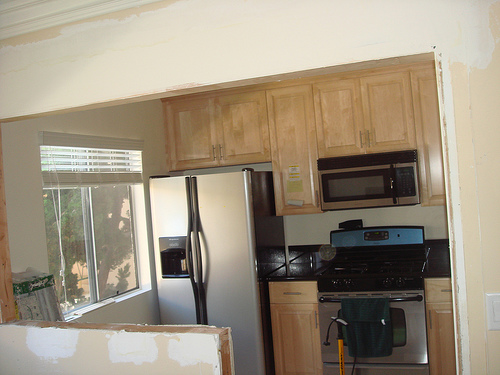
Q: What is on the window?
A: Shades.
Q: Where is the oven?
A: In a room.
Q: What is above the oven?
A: Microwave.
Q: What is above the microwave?
A: Cabinets.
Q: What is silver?
A: The fridge.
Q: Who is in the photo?
A: No people.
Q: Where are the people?
A: None in photo.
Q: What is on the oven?
A: Towel.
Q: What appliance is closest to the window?
A: Refrigerator.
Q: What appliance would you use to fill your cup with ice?
A: The freezer door by the window.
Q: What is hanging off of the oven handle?
A: Green towel.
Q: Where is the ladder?
A: Against the wall by the window.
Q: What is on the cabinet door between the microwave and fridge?
A: Stickers.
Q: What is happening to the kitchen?
A: Remodel.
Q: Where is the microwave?
A: Above the stove.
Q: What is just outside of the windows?
A: Trees.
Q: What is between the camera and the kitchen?
A: A half wall with patched drywall.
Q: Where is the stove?
A: Under the microwave.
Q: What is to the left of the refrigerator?
A: A window.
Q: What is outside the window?
A: A tree with green leaves.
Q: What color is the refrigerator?
A: Silver.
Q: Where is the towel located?
A: On the stove.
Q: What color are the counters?
A: Black.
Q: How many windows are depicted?
A: One.